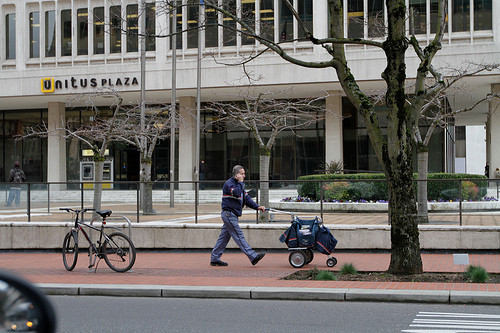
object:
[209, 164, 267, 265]
man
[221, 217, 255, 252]
leg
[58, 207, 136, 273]
bike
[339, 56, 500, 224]
tree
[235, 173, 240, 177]
phone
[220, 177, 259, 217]
jacket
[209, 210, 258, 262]
pants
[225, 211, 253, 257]
stripe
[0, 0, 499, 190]
building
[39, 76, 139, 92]
sign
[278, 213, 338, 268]
mail stroller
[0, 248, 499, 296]
sidewalk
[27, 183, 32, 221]
post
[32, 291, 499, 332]
road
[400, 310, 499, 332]
lettering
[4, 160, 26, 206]
man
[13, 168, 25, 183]
backpack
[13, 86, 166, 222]
tree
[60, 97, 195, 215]
tree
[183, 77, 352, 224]
tree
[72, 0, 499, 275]
tree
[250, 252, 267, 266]
foot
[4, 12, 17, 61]
windows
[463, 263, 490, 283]
plant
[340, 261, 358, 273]
plant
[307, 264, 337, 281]
plant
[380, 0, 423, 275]
trunk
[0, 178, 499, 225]
fence